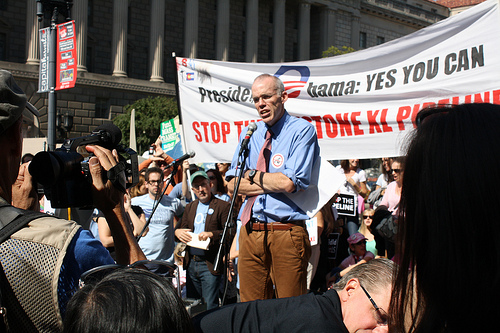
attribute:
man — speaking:
[233, 78, 310, 302]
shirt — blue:
[233, 110, 323, 216]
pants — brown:
[236, 222, 307, 296]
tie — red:
[240, 135, 270, 223]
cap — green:
[188, 171, 208, 177]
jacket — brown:
[177, 200, 231, 253]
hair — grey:
[256, 77, 289, 96]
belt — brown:
[245, 221, 299, 236]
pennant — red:
[57, 25, 76, 87]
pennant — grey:
[38, 25, 49, 93]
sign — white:
[170, 1, 498, 162]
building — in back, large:
[9, 2, 439, 152]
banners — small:
[35, 28, 80, 93]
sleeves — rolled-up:
[219, 139, 307, 185]